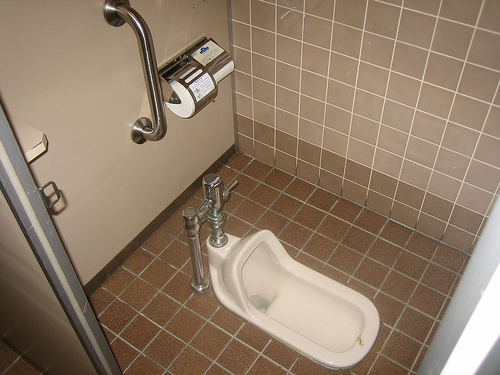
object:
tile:
[327, 18, 367, 63]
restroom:
[4, 3, 496, 373]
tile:
[391, 5, 441, 56]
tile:
[312, 210, 354, 244]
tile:
[142, 325, 192, 372]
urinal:
[198, 226, 387, 373]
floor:
[66, 150, 476, 373]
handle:
[221, 176, 246, 204]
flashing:
[224, 180, 240, 196]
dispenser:
[157, 57, 222, 120]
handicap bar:
[101, 2, 169, 146]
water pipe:
[206, 211, 230, 247]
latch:
[40, 178, 69, 216]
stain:
[356, 334, 364, 347]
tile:
[393, 301, 439, 344]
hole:
[252, 288, 271, 311]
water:
[260, 299, 266, 306]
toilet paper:
[166, 82, 196, 119]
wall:
[230, 2, 500, 259]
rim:
[256, 315, 326, 361]